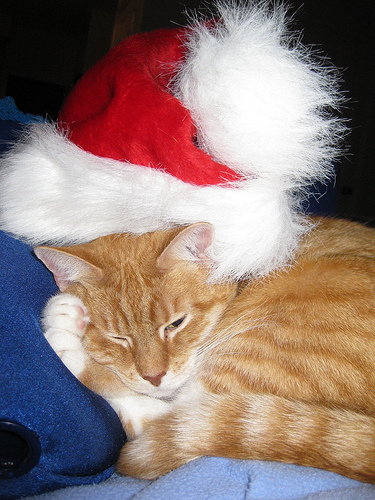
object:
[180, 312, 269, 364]
cat whiskers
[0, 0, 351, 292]
hat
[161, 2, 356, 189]
cotton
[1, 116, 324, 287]
cotton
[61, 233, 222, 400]
face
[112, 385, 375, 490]
tail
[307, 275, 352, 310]
fur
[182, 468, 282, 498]
blanket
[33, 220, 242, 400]
head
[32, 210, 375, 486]
cat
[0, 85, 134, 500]
pillow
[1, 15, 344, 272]
cloth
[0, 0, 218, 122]
wall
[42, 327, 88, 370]
paw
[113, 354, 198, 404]
mouth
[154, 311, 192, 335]
eye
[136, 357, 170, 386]
nose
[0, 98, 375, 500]
bed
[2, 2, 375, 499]
photo